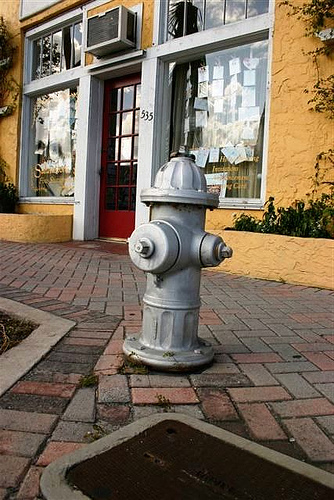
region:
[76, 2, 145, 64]
a window unit air conditioner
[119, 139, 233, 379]
a silver fire hydrant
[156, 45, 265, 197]
pictures hanging in window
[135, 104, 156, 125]
the numbers 535 on door frame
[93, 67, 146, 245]
a red front door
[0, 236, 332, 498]
a brick paved sidewalk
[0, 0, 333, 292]
a yellow painted building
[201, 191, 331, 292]
plants in the planter's box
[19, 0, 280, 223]
four windows around the door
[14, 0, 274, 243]
trim painted white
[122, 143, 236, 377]
silver fre hydrant on brick sidewalk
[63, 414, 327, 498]
metal sewer grate on sidewalk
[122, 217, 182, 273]
silver lug on side of fire hydrant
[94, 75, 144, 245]
red glass pane front door on building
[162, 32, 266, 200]
large store front window with paper designs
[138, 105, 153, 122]
number with black lettering on front of building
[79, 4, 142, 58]
airconditioning unit on top of red front door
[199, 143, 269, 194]
gold lettering on storefront window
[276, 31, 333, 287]
yellow exterior painted wall of building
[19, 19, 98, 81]
five panel short window on top of larger store front window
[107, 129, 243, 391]
silver fire hydrant in photograph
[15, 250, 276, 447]
brick side walk in photo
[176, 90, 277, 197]
many white papers in window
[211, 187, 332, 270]
plants on side of building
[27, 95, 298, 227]
two windows in photograph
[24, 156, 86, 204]
yellow writing on window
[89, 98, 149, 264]
red door in photograph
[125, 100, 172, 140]
black number 353 on white doorway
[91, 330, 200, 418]
grass growing through cracks in bricks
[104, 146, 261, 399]
silver metal fire hydrant in front of building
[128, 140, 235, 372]
this is a fire hydrant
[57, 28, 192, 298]
the door is red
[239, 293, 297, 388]
the sidewalk is brick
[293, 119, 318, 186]
the walls are stucco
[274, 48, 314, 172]
the wall is painted yellow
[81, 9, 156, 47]
this is an air conditioner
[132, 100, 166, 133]
the number is 535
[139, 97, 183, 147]
the numbers are black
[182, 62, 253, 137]
papers hanging in the window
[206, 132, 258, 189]
gold lettering on window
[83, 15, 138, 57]
The air conditioner over the red door.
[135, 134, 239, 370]
The gray fire hydrant on the sidewalk.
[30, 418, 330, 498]
The sewer drain on the sidewalk.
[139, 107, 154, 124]
The number 535 on the building.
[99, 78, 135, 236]
The red door of the building.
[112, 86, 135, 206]
The windows of the red door to the building.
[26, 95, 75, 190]
The big window to the left of the red door.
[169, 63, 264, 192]
The big window to the right of the red door.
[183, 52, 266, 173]
The white papers in the window to the right of the red door.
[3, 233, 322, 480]
The brick sidewalk in front of the building.